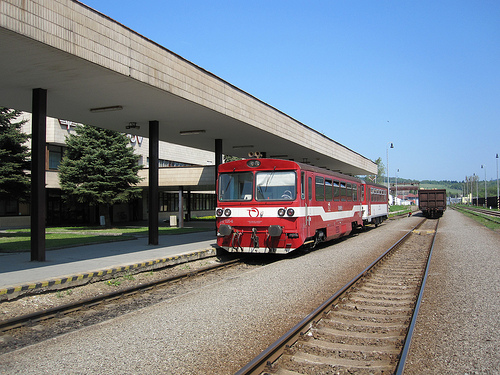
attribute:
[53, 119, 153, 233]
tree — tall, evergreen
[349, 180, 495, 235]
cart — black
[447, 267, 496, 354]
gravel — grey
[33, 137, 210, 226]
tree — green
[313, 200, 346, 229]
line — white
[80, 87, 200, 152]
lights — off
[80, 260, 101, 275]
stripes — faded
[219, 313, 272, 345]
tracks — grey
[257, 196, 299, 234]
train — red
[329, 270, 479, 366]
rail — silver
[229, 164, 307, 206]
window — clear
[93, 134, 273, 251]
pole — black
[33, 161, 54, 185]
pole — wooden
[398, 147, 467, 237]
carriage — rusty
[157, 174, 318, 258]
train — red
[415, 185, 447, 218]
train cart — brown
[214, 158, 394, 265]
train — red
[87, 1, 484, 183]
sky — clear, blue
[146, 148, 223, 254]
pillar — brown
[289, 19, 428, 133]
sky — blue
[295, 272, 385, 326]
tracks — metal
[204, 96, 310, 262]
train — red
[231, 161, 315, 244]
train — red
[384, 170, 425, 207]
roof — red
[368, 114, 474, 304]
pole — tall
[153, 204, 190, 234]
bin — white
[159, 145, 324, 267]
lights — off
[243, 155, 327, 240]
train — red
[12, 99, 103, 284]
beams — steel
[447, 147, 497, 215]
lights — tall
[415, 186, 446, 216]
carriage — metallic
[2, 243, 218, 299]
markings — yellow, black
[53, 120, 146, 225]
tree — green